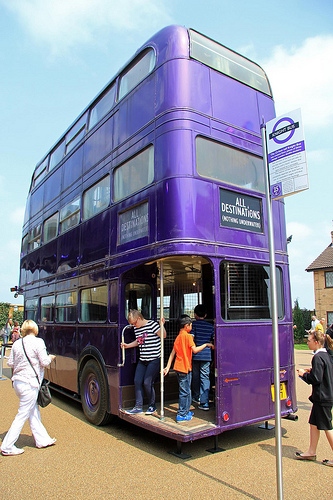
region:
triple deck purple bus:
[50, 30, 279, 452]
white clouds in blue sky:
[18, 10, 56, 55]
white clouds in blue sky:
[26, 89, 46, 106]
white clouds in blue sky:
[281, 43, 315, 70]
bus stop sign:
[237, 103, 328, 206]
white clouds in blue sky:
[14, 77, 58, 125]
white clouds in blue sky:
[271, 28, 330, 55]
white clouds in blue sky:
[271, 37, 327, 118]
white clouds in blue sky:
[24, 29, 74, 65]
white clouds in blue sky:
[91, 11, 119, 52]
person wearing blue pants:
[125, 305, 158, 413]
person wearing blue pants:
[169, 320, 201, 426]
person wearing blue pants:
[190, 306, 216, 414]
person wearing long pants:
[0, 321, 57, 454]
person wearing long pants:
[126, 310, 162, 416]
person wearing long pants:
[171, 317, 199, 426]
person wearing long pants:
[187, 304, 213, 409]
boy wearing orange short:
[163, 315, 195, 424]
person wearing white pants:
[0, 321, 58, 455]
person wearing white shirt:
[6, 321, 56, 453]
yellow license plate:
[267, 381, 287, 402]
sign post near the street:
[255, 95, 326, 264]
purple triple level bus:
[138, 33, 303, 493]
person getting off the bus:
[102, 302, 164, 413]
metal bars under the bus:
[169, 435, 227, 467]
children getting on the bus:
[169, 300, 224, 415]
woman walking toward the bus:
[5, 312, 77, 435]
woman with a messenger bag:
[18, 332, 57, 410]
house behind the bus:
[306, 251, 332, 332]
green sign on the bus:
[206, 184, 280, 247]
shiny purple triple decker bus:
[7, 18, 303, 459]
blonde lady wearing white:
[3, 319, 57, 458]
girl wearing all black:
[294, 329, 332, 472]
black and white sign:
[214, 182, 272, 235]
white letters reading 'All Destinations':
[218, 194, 263, 220]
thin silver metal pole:
[260, 118, 289, 499]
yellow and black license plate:
[267, 380, 287, 401]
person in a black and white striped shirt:
[117, 307, 164, 416]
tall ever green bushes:
[289, 295, 318, 342]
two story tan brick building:
[302, 230, 331, 338]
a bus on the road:
[5, 43, 312, 429]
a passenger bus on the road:
[18, 205, 234, 497]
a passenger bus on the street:
[24, 243, 301, 486]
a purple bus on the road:
[5, 258, 294, 483]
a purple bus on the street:
[5, 246, 318, 474]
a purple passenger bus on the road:
[18, 252, 331, 483]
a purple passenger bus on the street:
[19, 258, 307, 493]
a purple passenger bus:
[10, 303, 91, 457]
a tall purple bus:
[30, 202, 283, 495]